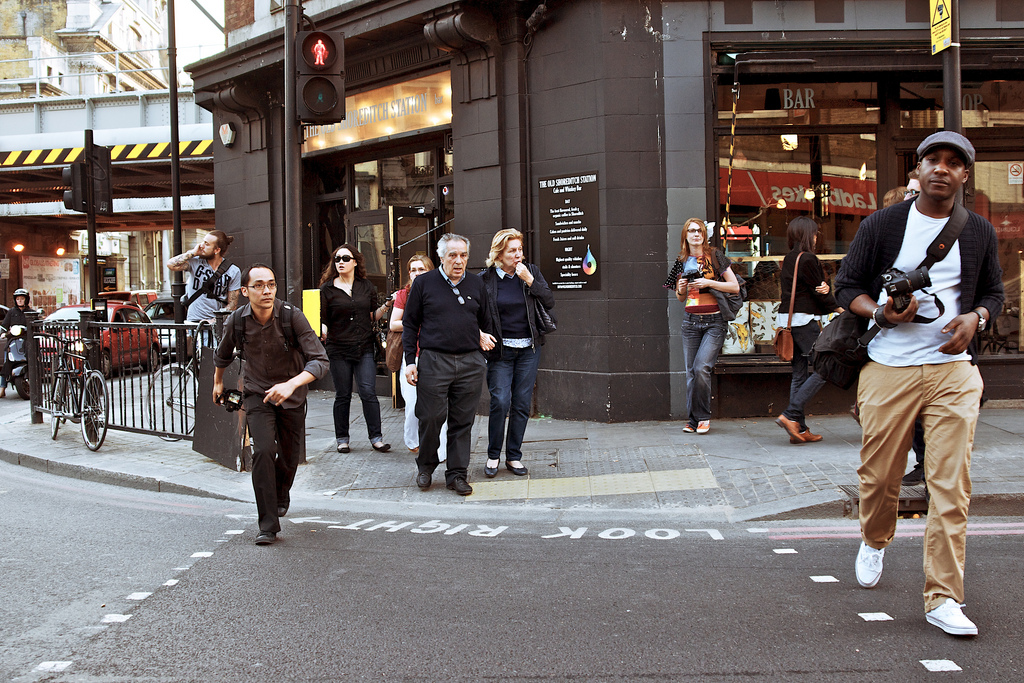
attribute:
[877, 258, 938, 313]
camera — black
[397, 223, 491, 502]
man — old 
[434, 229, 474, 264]
gray hair — gray 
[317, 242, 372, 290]
long hair — long 